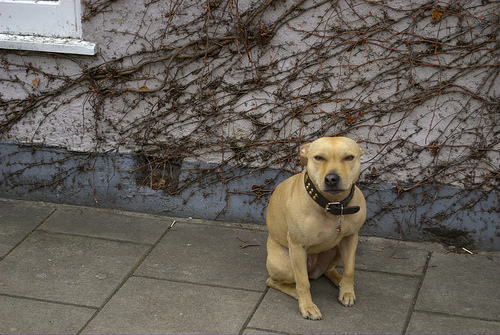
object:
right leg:
[287, 245, 319, 305]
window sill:
[0, 35, 98, 56]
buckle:
[323, 202, 346, 220]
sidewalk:
[0, 200, 499, 335]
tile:
[414, 255, 499, 315]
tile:
[335, 237, 428, 276]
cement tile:
[132, 220, 275, 292]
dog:
[259, 137, 370, 321]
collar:
[304, 169, 360, 215]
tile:
[35, 204, 176, 245]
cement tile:
[0, 230, 154, 311]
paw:
[324, 265, 342, 287]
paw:
[338, 283, 356, 308]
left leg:
[338, 231, 360, 288]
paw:
[296, 299, 323, 321]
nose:
[323, 172, 342, 187]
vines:
[105, 30, 182, 92]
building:
[0, 0, 499, 249]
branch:
[29, 90, 95, 143]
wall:
[0, 0, 499, 249]